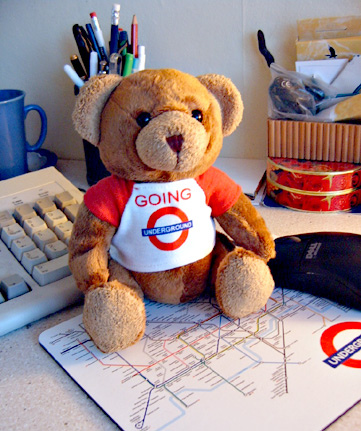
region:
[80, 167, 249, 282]
a red and white shirt on the bear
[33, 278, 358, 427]
a white mouse pad with a map on it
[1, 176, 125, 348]
a white keyboard on the desk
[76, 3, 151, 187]
a blue cup holding several pens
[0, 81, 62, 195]
a blue cup sitting on a plate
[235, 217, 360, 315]
a black Dell mouse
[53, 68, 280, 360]
a brown stuffed teddy bear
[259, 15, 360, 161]
a stack of small boxes and paper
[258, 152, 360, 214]
a round red can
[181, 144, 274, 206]
a stack of white note paper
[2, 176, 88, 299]
Numbers on a keyboard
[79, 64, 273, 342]
Stuffed teddy bear with an Underground shirt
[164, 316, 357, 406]
Section of the London Underground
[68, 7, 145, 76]
Writing utensils in a cup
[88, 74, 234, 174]
Stuffed teddy bear face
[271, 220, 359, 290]
Black computer mouse by Dell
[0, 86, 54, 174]
Blue coffee mug next to a keyboard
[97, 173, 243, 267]
Tiny "Going Underground" tee shirt on a bear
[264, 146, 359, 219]
Two boxes of chocolates next to a stuffed bear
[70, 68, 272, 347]
Brown stuffed bear wearing a tee shirt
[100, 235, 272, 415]
a stuffed toy teddy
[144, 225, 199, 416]
a stuffed toy teddy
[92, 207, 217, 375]
a stuffed toy teddy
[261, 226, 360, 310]
a black computer mouse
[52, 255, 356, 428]
a mouse pad with a red and blue logo on it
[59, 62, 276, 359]
stuffed teddy bear on edge of mouse pad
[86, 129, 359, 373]
bear is wearing a shirt with the same logo as the mouse pad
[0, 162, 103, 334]
a computer keyboard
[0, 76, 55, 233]
blue mug behind keyboard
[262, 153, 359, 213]
a box with red roses printed on it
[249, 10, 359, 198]
items piled on top of box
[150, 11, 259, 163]
white wall behind bear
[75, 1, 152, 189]
pens and pencils in a container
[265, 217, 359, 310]
the mouse is black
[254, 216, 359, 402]
mouse beside the map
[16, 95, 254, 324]
the keyboard behind bear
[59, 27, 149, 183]
pens in the cup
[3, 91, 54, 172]
the mug is blue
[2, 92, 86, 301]
mug behind the keyboard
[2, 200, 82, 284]
keys on the keyboard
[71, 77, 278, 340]
shirt on the bear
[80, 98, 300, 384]
bear is on the map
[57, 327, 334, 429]
the map is white